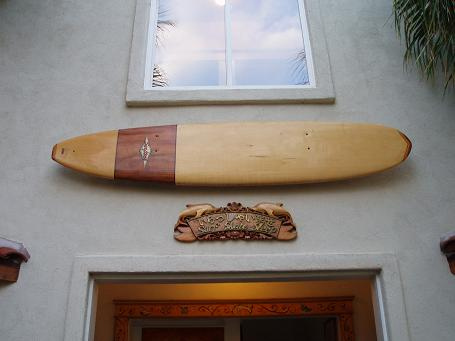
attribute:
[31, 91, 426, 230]
board — wooden, black, hanging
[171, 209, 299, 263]
sign — wooden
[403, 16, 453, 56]
tree — green, palm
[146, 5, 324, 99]
window — reflective, clear, reflection, reflecting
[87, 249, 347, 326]
doorway — wooden, double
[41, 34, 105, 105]
wall — cement, white